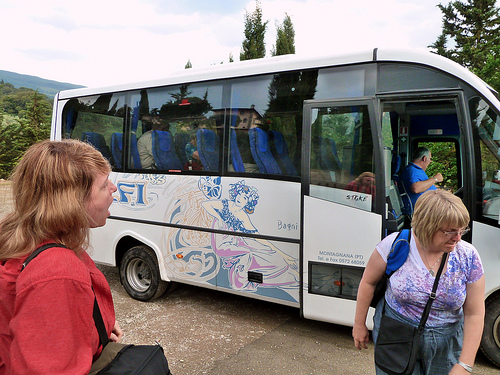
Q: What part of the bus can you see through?
A: Window.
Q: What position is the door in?
A: Open.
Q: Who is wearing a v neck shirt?
A: The woman.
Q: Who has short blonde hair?
A: The woman.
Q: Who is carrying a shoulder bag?
A: The woman.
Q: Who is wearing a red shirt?
A: The woman on the left.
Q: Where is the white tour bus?
A: Behind the women.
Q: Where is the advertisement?
A: On the side of the bus.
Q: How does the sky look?
A: Cloudy.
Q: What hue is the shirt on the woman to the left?
A: Red.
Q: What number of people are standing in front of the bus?
A: Two.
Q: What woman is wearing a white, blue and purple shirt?
A: The blonde woman with glasses.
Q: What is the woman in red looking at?
A: The bus.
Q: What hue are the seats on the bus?
A: Blue.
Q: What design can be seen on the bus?
A: A woman sitting.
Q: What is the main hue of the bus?
A: White.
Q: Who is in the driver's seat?
A: A man in a blue shirt.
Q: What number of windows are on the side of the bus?
A: Four.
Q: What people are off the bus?
A: The two woman.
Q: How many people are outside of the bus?
A: Two.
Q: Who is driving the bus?
A: Bus driver.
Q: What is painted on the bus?
A: A woman.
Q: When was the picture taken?
A: Daytime.